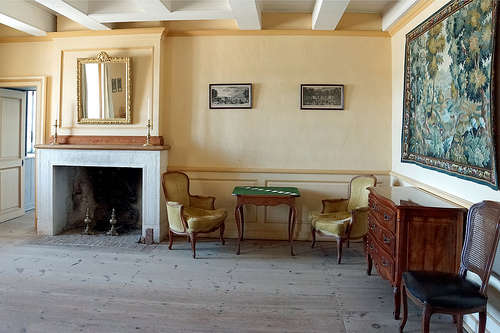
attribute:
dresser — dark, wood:
[356, 172, 472, 328]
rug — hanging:
[12, 199, 447, 326]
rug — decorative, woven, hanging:
[13, 205, 435, 333]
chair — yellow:
[147, 167, 239, 265]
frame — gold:
[81, 116, 136, 134]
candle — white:
[145, 118, 155, 126]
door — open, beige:
[0, 84, 22, 226]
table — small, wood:
[228, 172, 302, 275]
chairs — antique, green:
[155, 165, 382, 262]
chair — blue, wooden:
[371, 191, 486, 333]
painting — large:
[204, 79, 260, 115]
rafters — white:
[22, 50, 27, 56]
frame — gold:
[77, 118, 137, 132]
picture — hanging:
[204, 65, 264, 122]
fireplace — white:
[35, 122, 165, 254]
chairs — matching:
[162, 146, 381, 276]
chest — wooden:
[357, 170, 466, 333]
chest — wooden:
[345, 168, 469, 330]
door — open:
[1, 87, 28, 227]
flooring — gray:
[1, 206, 470, 331]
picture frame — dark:
[208, 81, 254, 109]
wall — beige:
[0, 33, 391, 242]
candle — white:
[145, 94, 151, 120]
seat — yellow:
[180, 203, 228, 233]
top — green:
[230, 184, 300, 199]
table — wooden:
[230, 184, 301, 257]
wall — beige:
[390, 1, 483, 319]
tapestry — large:
[397, 1, 485, 188]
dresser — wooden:
[360, 182, 468, 321]